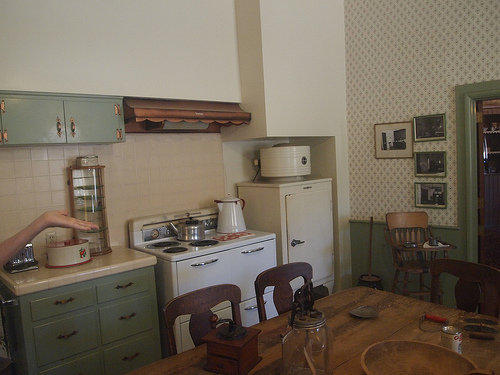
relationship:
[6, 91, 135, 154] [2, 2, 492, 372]
cabinets in kitchen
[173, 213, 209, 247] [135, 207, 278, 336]
teapot on stove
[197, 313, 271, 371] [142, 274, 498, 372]
grinder on table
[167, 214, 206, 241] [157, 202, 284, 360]
teapot on stove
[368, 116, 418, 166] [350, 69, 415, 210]
painting on wall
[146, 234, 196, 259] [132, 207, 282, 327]
burners on stove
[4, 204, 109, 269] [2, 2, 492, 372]
hand welcome kitchen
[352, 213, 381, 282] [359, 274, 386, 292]
broom next pan